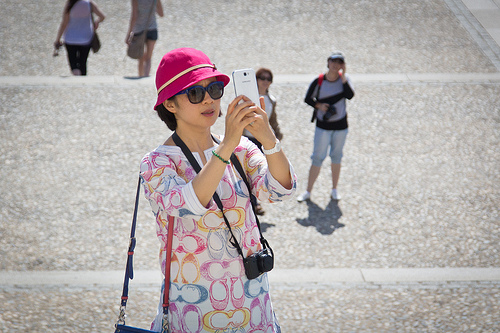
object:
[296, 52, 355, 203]
person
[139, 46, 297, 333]
woman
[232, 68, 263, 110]
camera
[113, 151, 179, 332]
bag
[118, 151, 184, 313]
strap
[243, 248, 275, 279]
camera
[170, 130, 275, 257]
strap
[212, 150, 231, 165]
bracelet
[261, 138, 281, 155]
watch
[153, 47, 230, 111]
hat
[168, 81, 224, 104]
glasses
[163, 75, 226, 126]
face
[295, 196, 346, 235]
shadow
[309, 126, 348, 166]
shorts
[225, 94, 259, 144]
hand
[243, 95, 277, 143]
hand